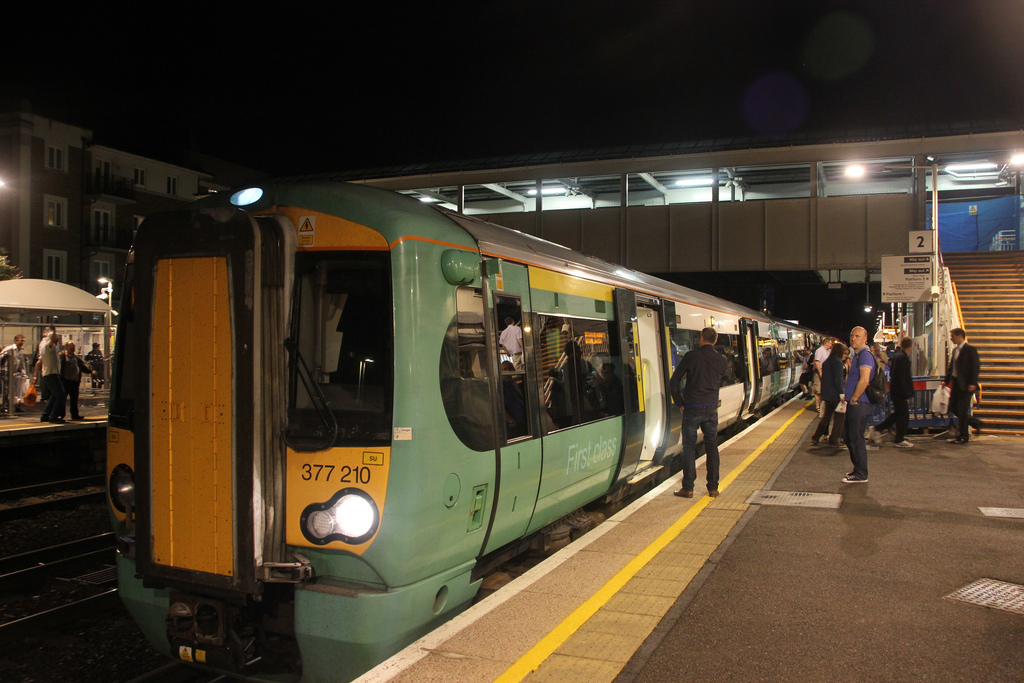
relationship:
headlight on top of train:
[335, 492, 375, 543] [103, 182, 832, 681]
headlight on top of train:
[112, 457, 134, 512] [103, 182, 832, 681]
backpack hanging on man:
[857, 352, 893, 398] [844, 325, 877, 481]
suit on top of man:
[949, 346, 980, 433] [940, 328, 988, 443]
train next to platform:
[103, 182, 832, 681] [347, 385, 1023, 680]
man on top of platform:
[844, 325, 877, 481] [347, 385, 1023, 680]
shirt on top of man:
[844, 349, 878, 403] [844, 325, 877, 481]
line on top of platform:
[497, 391, 818, 680] [347, 385, 1023, 680]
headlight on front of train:
[335, 492, 375, 543] [103, 182, 832, 681]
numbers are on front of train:
[301, 460, 373, 484] [103, 182, 832, 681]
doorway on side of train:
[637, 307, 662, 463] [103, 182, 832, 681]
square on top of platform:
[943, 579, 1022, 618] [347, 385, 1023, 680]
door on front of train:
[153, 255, 243, 580] [103, 182, 832, 681]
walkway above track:
[283, 120, 1024, 273] [3, 469, 165, 677]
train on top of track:
[103, 182, 832, 681] [3, 469, 165, 677]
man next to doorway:
[667, 327, 731, 498] [637, 307, 662, 463]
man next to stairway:
[940, 328, 988, 443] [943, 252, 1024, 433]